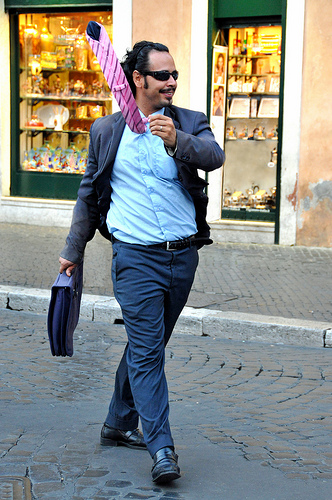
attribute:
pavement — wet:
[213, 377, 295, 454]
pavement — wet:
[215, 426, 285, 476]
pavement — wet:
[182, 385, 308, 491]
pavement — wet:
[192, 374, 316, 495]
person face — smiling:
[121, 40, 190, 108]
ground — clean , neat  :
[9, 424, 99, 497]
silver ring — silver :
[157, 123, 164, 131]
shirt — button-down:
[110, 112, 193, 241]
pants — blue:
[131, 341, 156, 377]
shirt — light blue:
[110, 120, 195, 247]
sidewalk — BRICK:
[4, 222, 320, 316]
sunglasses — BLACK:
[143, 68, 178, 80]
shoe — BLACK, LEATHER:
[151, 446, 181, 482]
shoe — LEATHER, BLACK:
[97, 420, 142, 450]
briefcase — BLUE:
[43, 261, 84, 358]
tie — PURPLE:
[84, 18, 146, 135]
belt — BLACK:
[140, 232, 200, 254]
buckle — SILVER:
[166, 239, 178, 252]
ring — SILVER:
[158, 124, 165, 131]